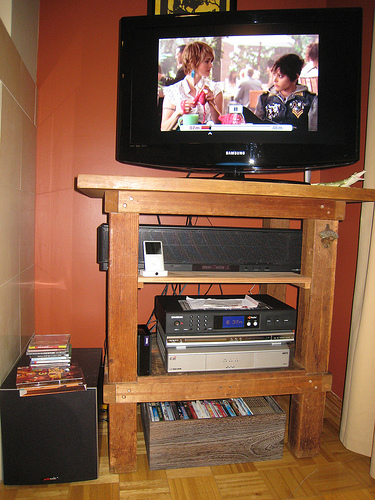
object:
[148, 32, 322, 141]
screen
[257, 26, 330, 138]
part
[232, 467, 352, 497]
floor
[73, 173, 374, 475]
stand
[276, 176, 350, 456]
part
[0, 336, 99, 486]
speaker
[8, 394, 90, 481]
part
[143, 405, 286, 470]
box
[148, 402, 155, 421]
books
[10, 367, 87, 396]
pile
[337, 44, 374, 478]
curtain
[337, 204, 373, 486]
part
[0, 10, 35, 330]
wall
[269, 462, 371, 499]
part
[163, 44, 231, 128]
lady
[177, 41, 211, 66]
hair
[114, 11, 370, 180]
television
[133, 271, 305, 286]
shelf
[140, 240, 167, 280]
ipod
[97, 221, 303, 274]
speaker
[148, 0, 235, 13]
picture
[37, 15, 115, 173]
wall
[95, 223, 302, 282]
electronics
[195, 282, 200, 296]
wires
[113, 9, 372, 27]
edge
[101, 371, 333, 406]
wood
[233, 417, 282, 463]
part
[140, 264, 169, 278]
charger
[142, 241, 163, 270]
phone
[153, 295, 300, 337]
cable box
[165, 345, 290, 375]
dvd player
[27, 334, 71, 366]
stack